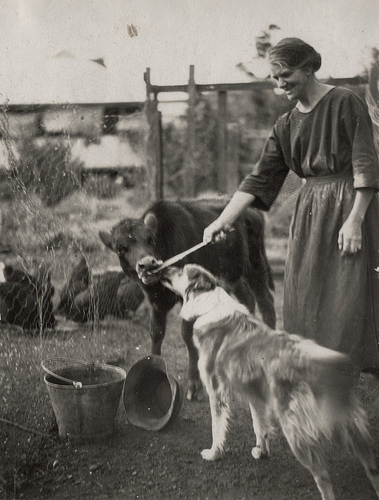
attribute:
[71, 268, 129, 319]
chikens — black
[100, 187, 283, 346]
calf — black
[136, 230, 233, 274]
stick — wooden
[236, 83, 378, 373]
dress — long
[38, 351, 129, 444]
pail — metal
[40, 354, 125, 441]
bucket — metal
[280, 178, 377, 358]
dress — long